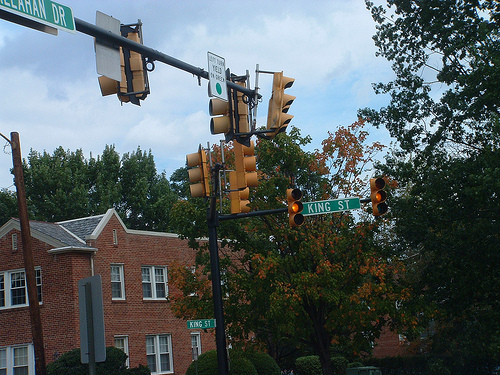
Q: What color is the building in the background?
A: Brown.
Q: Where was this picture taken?
A: Street corner.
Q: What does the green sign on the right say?
A: King St.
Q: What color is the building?
A: Red.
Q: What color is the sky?
A: Light blue.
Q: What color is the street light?
A: Yellow.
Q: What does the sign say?
A: King St.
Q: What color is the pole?
A: Black.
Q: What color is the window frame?
A: White.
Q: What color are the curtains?
A: White.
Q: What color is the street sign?
A: Green and white.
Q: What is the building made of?
A: Bricks.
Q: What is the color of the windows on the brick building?
A: White.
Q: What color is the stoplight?
A: Yellow.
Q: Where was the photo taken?
A: King St.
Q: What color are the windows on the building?
A: White.